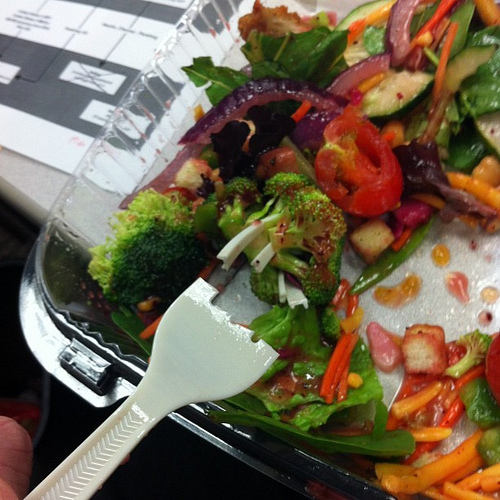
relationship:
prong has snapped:
[217, 221, 274, 272] [199, 205, 306, 354]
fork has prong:
[55, 298, 283, 482] [215, 207, 288, 268]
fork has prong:
[55, 298, 283, 482] [217, 221, 274, 272]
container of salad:
[42, 57, 486, 490] [202, 47, 441, 190]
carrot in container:
[443, 169, 481, 190] [42, 57, 486, 490]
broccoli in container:
[254, 195, 379, 373] [42, 57, 486, 490]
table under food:
[17, 156, 118, 244] [254, 110, 467, 276]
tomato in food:
[302, 144, 386, 193] [254, 110, 467, 276]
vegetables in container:
[249, 47, 407, 287] [42, 57, 486, 490]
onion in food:
[241, 68, 332, 93] [254, 110, 467, 276]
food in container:
[254, 110, 467, 276] [42, 57, 486, 490]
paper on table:
[15, 23, 182, 154] [17, 156, 118, 244]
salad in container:
[202, 47, 441, 190] [42, 57, 486, 490]